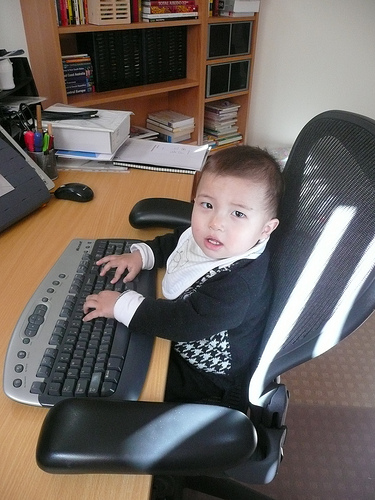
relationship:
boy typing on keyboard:
[79, 144, 283, 405] [5, 235, 159, 404]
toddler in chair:
[79, 144, 283, 405] [35, 109, 368, 499]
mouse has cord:
[52, 183, 95, 202] [49, 189, 58, 197]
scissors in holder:
[14, 103, 37, 135] [20, 150, 58, 180]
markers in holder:
[15, 129, 55, 152] [20, 150, 58, 180]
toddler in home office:
[79, 144, 283, 405] [2, 5, 374, 499]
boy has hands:
[79, 144, 283, 405] [77, 251, 145, 322]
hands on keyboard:
[77, 251, 145, 322] [5, 235, 159, 404]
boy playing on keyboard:
[79, 144, 283, 405] [5, 235, 159, 404]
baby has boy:
[79, 144, 283, 405] [79, 144, 283, 405]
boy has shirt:
[79, 144, 283, 405] [114, 227, 270, 390]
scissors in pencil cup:
[14, 103, 37, 135] [20, 150, 58, 180]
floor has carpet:
[151, 308, 374, 498] [149, 313, 374, 497]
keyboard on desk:
[5, 235, 159, 404] [2, 170, 193, 499]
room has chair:
[2, 5, 374, 499] [35, 109, 368, 499]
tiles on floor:
[149, 313, 374, 497] [151, 308, 374, 498]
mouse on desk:
[52, 183, 95, 202] [2, 170, 193, 499]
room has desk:
[2, 5, 374, 499] [2, 170, 193, 499]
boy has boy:
[79, 144, 283, 405] [79, 144, 283, 405]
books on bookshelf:
[59, 2, 197, 142] [16, 2, 205, 151]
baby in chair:
[79, 144, 283, 405] [35, 109, 368, 499]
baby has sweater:
[79, 144, 283, 405] [114, 227, 270, 390]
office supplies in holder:
[7, 104, 54, 151] [20, 150, 58, 180]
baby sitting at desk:
[79, 144, 283, 405] [2, 170, 193, 499]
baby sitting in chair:
[79, 144, 283, 405] [35, 109, 368, 499]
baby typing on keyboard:
[79, 144, 283, 405] [5, 235, 159, 404]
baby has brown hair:
[79, 144, 283, 405] [199, 145, 282, 218]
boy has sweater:
[79, 144, 283, 405] [114, 227, 270, 390]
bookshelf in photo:
[16, 2, 205, 151] [4, 5, 310, 420]